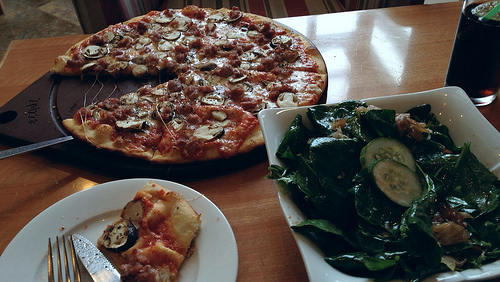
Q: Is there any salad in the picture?
A: Yes, there is salad.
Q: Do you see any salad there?
A: Yes, there is salad.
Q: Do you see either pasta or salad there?
A: Yes, there is salad.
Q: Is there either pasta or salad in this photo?
A: Yes, there is salad.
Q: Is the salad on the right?
A: Yes, the salad is on the right of the image.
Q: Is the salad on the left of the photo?
A: No, the salad is on the right of the image.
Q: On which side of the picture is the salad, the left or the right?
A: The salad is on the right of the image.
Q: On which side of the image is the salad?
A: The salad is on the right of the image.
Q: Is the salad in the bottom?
A: Yes, the salad is in the bottom of the image.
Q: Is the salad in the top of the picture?
A: No, the salad is in the bottom of the image.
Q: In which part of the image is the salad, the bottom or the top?
A: The salad is in the bottom of the image.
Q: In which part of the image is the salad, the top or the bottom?
A: The salad is in the bottom of the image.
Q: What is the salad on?
A: The salad is on the plate.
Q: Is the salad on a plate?
A: Yes, the salad is on a plate.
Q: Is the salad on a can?
A: No, the salad is on a plate.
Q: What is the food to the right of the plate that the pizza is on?
A: The food is salad.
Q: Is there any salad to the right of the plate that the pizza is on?
A: Yes, there is salad to the right of the plate.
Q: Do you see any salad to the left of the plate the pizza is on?
A: No, the salad is to the right of the plate.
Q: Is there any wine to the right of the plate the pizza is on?
A: No, there is salad to the right of the plate.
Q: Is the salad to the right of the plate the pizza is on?
A: Yes, the salad is to the right of the plate.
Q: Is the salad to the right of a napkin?
A: No, the salad is to the right of the plate.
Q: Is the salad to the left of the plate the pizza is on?
A: No, the salad is to the right of the plate.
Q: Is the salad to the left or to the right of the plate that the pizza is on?
A: The salad is to the right of the plate.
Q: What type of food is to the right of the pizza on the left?
A: The food is salad.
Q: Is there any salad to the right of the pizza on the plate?
A: Yes, there is salad to the right of the pizza.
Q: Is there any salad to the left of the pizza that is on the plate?
A: No, the salad is to the right of the pizza.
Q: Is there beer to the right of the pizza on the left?
A: No, there is salad to the right of the pizza.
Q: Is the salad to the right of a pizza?
A: Yes, the salad is to the right of a pizza.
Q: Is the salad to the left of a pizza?
A: No, the salad is to the right of a pizza.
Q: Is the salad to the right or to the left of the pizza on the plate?
A: The salad is to the right of the pizza.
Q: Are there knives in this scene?
A: Yes, there is a knife.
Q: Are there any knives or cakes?
A: Yes, there is a knife.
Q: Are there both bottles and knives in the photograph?
A: No, there is a knife but no bottles.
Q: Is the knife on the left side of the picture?
A: Yes, the knife is on the left of the image.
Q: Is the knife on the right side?
A: No, the knife is on the left of the image.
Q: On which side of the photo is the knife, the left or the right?
A: The knife is on the left of the image.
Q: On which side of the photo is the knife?
A: The knife is on the left of the image.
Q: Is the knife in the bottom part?
A: Yes, the knife is in the bottom of the image.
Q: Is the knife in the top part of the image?
A: No, the knife is in the bottom of the image.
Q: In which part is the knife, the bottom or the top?
A: The knife is in the bottom of the image.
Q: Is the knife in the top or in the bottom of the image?
A: The knife is in the bottom of the image.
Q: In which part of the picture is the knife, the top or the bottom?
A: The knife is in the bottom of the image.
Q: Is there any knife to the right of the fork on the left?
A: Yes, there is a knife to the right of the fork.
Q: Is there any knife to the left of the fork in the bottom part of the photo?
A: No, the knife is to the right of the fork.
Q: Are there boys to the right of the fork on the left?
A: No, there is a knife to the right of the fork.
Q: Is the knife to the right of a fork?
A: Yes, the knife is to the right of a fork.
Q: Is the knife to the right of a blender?
A: No, the knife is to the right of a fork.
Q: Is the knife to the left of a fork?
A: No, the knife is to the right of a fork.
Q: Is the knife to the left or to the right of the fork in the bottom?
A: The knife is to the right of the fork.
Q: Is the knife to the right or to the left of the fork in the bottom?
A: The knife is to the right of the fork.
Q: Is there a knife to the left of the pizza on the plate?
A: Yes, there is a knife to the left of the pizza.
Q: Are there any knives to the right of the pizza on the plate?
A: No, the knife is to the left of the pizza.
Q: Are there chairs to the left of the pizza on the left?
A: No, there is a knife to the left of the pizza.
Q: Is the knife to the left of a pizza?
A: Yes, the knife is to the left of a pizza.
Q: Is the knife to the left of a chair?
A: No, the knife is to the left of a pizza.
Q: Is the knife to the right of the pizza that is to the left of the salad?
A: No, the knife is to the left of the pizza.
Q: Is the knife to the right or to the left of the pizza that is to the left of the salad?
A: The knife is to the left of the pizza.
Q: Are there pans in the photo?
A: Yes, there is a pan.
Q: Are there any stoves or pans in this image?
A: Yes, there is a pan.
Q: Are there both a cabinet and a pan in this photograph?
A: No, there is a pan but no cabinets.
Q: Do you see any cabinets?
A: No, there are no cabinets.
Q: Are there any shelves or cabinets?
A: No, there are no cabinets or shelves.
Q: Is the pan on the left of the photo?
A: Yes, the pan is on the left of the image.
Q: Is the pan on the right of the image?
A: No, the pan is on the left of the image.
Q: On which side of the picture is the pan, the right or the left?
A: The pan is on the left of the image.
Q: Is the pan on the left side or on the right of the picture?
A: The pan is on the left of the image.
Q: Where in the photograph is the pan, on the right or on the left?
A: The pan is on the left of the image.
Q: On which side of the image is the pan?
A: The pan is on the left of the image.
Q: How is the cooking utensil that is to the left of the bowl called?
A: The cooking utensil is a pan.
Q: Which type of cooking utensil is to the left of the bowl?
A: The cooking utensil is a pan.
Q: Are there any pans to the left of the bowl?
A: Yes, there is a pan to the left of the bowl.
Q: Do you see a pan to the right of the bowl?
A: No, the pan is to the left of the bowl.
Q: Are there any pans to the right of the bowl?
A: No, the pan is to the left of the bowl.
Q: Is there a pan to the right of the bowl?
A: No, the pan is to the left of the bowl.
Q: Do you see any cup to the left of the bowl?
A: No, there is a pan to the left of the bowl.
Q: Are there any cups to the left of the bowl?
A: No, there is a pan to the left of the bowl.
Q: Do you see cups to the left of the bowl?
A: No, there is a pan to the left of the bowl.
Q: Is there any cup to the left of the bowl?
A: No, there is a pan to the left of the bowl.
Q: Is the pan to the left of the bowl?
A: Yes, the pan is to the left of the bowl.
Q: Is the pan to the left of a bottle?
A: No, the pan is to the left of the bowl.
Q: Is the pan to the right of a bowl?
A: No, the pan is to the left of a bowl.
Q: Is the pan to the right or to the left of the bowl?
A: The pan is to the left of the bowl.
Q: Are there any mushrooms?
A: Yes, there are mushrooms.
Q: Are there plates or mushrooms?
A: Yes, there are mushrooms.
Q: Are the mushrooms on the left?
A: Yes, the mushrooms are on the left of the image.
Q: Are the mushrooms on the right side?
A: No, the mushrooms are on the left of the image.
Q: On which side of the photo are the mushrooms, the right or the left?
A: The mushrooms are on the left of the image.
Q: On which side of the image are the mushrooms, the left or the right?
A: The mushrooms are on the left of the image.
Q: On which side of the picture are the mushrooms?
A: The mushrooms are on the left of the image.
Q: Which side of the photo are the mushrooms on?
A: The mushrooms are on the left of the image.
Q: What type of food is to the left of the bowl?
A: The food is mushrooms.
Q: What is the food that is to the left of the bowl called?
A: The food is mushrooms.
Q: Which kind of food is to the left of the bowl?
A: The food is mushrooms.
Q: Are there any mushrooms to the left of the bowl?
A: Yes, there are mushrooms to the left of the bowl.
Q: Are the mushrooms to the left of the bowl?
A: Yes, the mushrooms are to the left of the bowl.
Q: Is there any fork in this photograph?
A: Yes, there is a fork.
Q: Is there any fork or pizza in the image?
A: Yes, there is a fork.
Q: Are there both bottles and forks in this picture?
A: No, there is a fork but no bottles.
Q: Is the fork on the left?
A: Yes, the fork is on the left of the image.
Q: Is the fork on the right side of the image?
A: No, the fork is on the left of the image.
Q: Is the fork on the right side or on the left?
A: The fork is on the left of the image.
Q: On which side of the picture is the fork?
A: The fork is on the left of the image.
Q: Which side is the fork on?
A: The fork is on the left of the image.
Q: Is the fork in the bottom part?
A: Yes, the fork is in the bottom of the image.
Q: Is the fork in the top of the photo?
A: No, the fork is in the bottom of the image.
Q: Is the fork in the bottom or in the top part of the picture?
A: The fork is in the bottom of the image.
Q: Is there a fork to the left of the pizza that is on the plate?
A: Yes, there is a fork to the left of the pizza.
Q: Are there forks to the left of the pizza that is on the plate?
A: Yes, there is a fork to the left of the pizza.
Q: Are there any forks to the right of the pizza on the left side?
A: No, the fork is to the left of the pizza.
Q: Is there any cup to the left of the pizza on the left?
A: No, there is a fork to the left of the pizza.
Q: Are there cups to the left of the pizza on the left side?
A: No, there is a fork to the left of the pizza.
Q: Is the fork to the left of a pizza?
A: Yes, the fork is to the left of a pizza.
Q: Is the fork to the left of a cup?
A: No, the fork is to the left of a pizza.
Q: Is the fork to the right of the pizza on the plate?
A: No, the fork is to the left of the pizza.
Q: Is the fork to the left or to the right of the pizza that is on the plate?
A: The fork is to the left of the pizza.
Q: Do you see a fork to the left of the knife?
A: Yes, there is a fork to the left of the knife.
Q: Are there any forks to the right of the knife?
A: No, the fork is to the left of the knife.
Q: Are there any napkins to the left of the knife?
A: No, there is a fork to the left of the knife.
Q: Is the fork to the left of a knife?
A: Yes, the fork is to the left of a knife.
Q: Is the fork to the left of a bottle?
A: No, the fork is to the left of a knife.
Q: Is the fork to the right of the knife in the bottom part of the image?
A: No, the fork is to the left of the knife.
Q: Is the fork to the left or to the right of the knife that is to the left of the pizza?
A: The fork is to the left of the knife.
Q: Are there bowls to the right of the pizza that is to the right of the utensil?
A: Yes, there is a bowl to the right of the pizza.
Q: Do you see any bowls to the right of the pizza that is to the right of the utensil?
A: Yes, there is a bowl to the right of the pizza.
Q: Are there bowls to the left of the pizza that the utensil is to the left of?
A: No, the bowl is to the right of the pizza.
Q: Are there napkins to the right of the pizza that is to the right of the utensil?
A: No, there is a bowl to the right of the pizza.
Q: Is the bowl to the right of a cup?
A: No, the bowl is to the right of a pizza.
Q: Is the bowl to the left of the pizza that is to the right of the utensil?
A: No, the bowl is to the right of the pizza.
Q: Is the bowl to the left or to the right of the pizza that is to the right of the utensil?
A: The bowl is to the right of the pizza.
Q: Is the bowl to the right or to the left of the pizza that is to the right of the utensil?
A: The bowl is to the right of the pizza.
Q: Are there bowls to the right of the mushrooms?
A: Yes, there is a bowl to the right of the mushrooms.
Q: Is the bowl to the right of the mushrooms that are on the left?
A: Yes, the bowl is to the right of the mushrooms.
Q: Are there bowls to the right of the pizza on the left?
A: Yes, there is a bowl to the right of the pizza.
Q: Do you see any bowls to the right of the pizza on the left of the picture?
A: Yes, there is a bowl to the right of the pizza.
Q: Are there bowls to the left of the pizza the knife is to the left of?
A: No, the bowl is to the right of the pizza.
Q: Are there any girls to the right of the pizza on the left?
A: No, there is a bowl to the right of the pizza.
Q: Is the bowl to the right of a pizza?
A: Yes, the bowl is to the right of a pizza.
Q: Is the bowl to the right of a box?
A: No, the bowl is to the right of a pizza.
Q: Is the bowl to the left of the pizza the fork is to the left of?
A: No, the bowl is to the right of the pizza.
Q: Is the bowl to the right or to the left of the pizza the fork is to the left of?
A: The bowl is to the right of the pizza.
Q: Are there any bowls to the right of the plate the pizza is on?
A: Yes, there is a bowl to the right of the plate.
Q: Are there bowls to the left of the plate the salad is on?
A: No, the bowl is to the right of the plate.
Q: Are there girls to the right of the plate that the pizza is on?
A: No, there is a bowl to the right of the plate.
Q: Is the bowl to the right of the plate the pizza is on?
A: Yes, the bowl is to the right of the plate.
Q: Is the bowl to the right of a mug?
A: No, the bowl is to the right of the plate.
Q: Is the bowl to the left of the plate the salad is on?
A: No, the bowl is to the right of the plate.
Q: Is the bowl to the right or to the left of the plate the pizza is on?
A: The bowl is to the right of the plate.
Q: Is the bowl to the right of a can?
A: No, the bowl is to the right of the plate.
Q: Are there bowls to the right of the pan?
A: Yes, there is a bowl to the right of the pan.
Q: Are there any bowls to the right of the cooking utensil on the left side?
A: Yes, there is a bowl to the right of the pan.